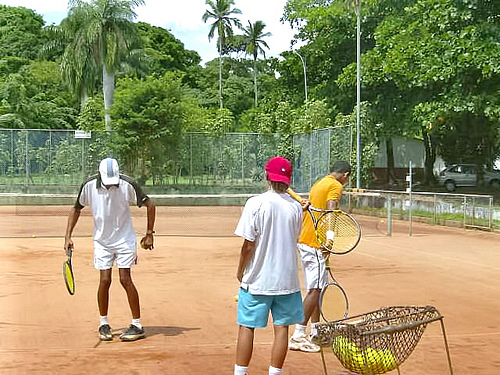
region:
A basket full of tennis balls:
[316, 303, 455, 374]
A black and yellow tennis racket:
[61, 247, 76, 297]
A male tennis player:
[63, 157, 158, 341]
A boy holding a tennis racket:
[233, 157, 363, 374]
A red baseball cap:
[265, 155, 292, 185]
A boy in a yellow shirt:
[299, 159, 352, 352]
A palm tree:
[53, 0, 145, 137]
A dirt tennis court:
[2, 202, 499, 374]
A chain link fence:
[1, 127, 493, 234]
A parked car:
[438, 162, 499, 192]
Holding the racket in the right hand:
[60, 236, 77, 296]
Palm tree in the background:
[55, 0, 159, 132]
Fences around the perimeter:
[3, 124, 494, 234]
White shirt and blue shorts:
[235, 188, 305, 328]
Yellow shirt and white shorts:
[295, 173, 341, 294]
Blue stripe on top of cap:
[95, 156, 122, 188]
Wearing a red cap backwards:
[263, 154, 294, 187]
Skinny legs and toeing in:
[96, 268, 147, 345]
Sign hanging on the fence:
[72, 129, 94, 140]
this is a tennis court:
[19, 38, 459, 308]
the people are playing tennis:
[53, 96, 445, 339]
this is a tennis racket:
[15, 238, 105, 311]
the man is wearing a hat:
[77, 155, 147, 202]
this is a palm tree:
[69, 29, 136, 171]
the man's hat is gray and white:
[98, 159, 126, 179]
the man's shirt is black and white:
[66, 174, 150, 244]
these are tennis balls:
[323, 327, 403, 372]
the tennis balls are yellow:
[319, 319, 406, 364]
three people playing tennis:
[45, 131, 388, 374]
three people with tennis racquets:
[50, 135, 360, 365]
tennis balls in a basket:
[303, 303, 443, 374]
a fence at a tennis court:
[10, 117, 362, 191]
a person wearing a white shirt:
[238, 189, 306, 294]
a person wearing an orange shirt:
[300, 171, 341, 248]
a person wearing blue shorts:
[228, 281, 310, 332]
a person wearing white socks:
[230, 363, 283, 374]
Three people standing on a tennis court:
[2, 150, 497, 372]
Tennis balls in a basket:
[311, 295, 453, 370]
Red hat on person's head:
[257, 150, 294, 195]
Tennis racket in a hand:
[55, 231, 80, 293]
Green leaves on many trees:
[0, 0, 496, 145]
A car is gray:
[430, 157, 495, 192]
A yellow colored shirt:
[295, 170, 345, 252]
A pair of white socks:
[91, 310, 146, 330]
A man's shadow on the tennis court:
[90, 317, 201, 347]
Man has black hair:
[326, 150, 356, 188]